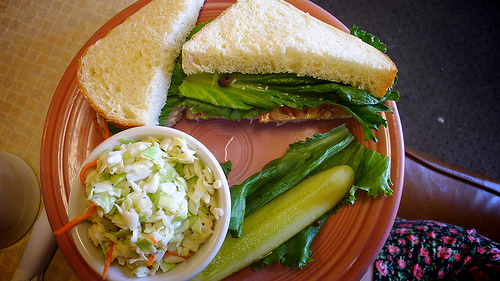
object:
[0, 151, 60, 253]
cup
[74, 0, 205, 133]
sandwich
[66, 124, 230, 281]
bowl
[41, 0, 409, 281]
plate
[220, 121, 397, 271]
lettuce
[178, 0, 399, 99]
bread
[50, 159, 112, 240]
carrot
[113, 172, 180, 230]
cabbage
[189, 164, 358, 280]
spear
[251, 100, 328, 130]
pail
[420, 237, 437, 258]
flower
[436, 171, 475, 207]
couch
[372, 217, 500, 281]
dress